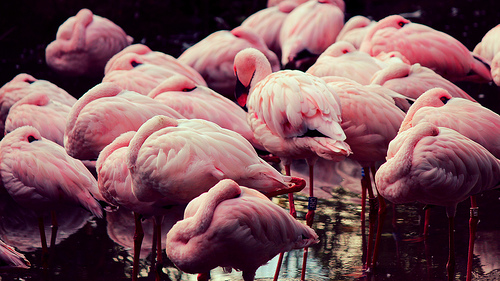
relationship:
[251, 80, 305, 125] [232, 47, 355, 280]
wing of a bird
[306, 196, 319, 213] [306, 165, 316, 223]
tag attached to leg